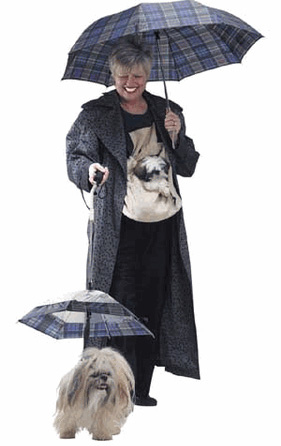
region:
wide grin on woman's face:
[120, 83, 163, 91]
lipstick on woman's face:
[115, 83, 142, 96]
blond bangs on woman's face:
[109, 54, 155, 80]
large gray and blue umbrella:
[70, 3, 272, 92]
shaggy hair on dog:
[63, 360, 94, 412]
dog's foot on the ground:
[49, 422, 118, 440]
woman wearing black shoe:
[132, 392, 161, 410]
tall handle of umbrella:
[154, 42, 179, 108]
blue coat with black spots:
[64, 105, 120, 156]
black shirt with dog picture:
[114, 119, 185, 223]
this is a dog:
[56, 350, 135, 440]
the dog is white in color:
[82, 408, 97, 422]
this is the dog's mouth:
[94, 379, 111, 390]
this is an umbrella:
[16, 293, 152, 337]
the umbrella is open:
[22, 305, 138, 339]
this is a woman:
[65, 44, 205, 405]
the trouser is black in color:
[124, 232, 162, 254]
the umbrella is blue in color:
[163, 6, 195, 20]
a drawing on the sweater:
[135, 148, 177, 200]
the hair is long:
[112, 362, 126, 387]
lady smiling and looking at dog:
[103, 50, 156, 107]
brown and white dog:
[53, 353, 133, 439]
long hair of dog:
[53, 348, 127, 425]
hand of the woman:
[155, 98, 187, 142]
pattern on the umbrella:
[177, 38, 219, 72]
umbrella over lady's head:
[70, 2, 251, 83]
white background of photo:
[196, 123, 259, 190]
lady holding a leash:
[76, 158, 116, 201]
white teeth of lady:
[119, 86, 143, 98]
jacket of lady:
[78, 101, 131, 149]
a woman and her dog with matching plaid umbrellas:
[13, 37, 234, 444]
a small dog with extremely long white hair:
[49, 352, 152, 444]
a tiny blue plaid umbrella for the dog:
[16, 283, 157, 347]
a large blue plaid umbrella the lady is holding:
[48, 0, 267, 92]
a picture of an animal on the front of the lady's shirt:
[116, 135, 183, 223]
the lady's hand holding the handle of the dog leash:
[83, 163, 111, 198]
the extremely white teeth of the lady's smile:
[124, 87, 137, 91]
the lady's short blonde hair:
[112, 45, 153, 73]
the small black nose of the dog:
[100, 375, 108, 381]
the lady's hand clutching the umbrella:
[161, 104, 187, 136]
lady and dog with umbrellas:
[62, 4, 270, 406]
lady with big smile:
[95, 39, 160, 105]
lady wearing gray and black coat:
[70, 48, 216, 320]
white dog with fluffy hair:
[52, 349, 146, 441]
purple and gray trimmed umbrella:
[7, 276, 169, 350]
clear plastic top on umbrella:
[28, 283, 152, 353]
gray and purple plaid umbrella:
[78, 3, 243, 101]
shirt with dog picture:
[72, 89, 208, 241]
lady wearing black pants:
[87, 53, 221, 345]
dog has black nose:
[72, 344, 139, 411]